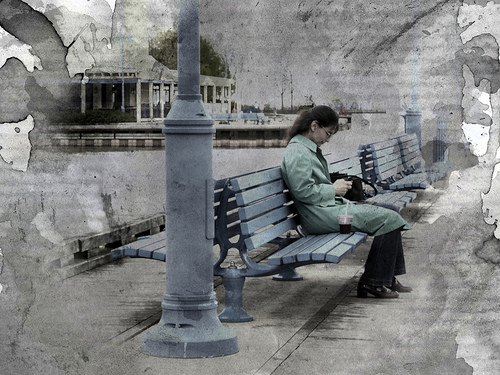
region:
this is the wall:
[271, 8, 387, 82]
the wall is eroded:
[257, 10, 493, 103]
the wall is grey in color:
[256, 19, 334, 66]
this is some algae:
[199, 43, 219, 73]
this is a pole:
[162, 5, 217, 330]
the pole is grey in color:
[171, 148, 199, 202]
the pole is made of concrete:
[176, 135, 204, 191]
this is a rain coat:
[301, 159, 313, 179]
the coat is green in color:
[293, 150, 306, 169]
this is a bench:
[243, 195, 294, 261]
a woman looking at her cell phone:
[280, 98, 400, 248]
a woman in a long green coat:
[278, 118, 405, 240]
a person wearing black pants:
[365, 233, 417, 277]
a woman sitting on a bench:
[222, 105, 395, 277]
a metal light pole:
[145, 20, 232, 331]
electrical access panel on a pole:
[197, 175, 219, 247]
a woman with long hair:
[280, 98, 347, 149]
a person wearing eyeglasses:
[320, 123, 336, 141]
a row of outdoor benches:
[176, 115, 435, 283]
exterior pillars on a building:
[83, 83, 170, 116]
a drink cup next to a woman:
[336, 198, 356, 234]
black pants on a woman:
[364, 224, 415, 285]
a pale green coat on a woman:
[280, 133, 406, 235]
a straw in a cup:
[342, 199, 351, 226]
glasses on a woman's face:
[319, 125, 336, 141]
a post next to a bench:
[138, 0, 241, 360]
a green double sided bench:
[112, 161, 408, 323]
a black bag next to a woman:
[324, 171, 380, 199]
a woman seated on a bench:
[280, 94, 413, 304]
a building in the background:
[48, 58, 252, 131]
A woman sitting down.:
[280, 102, 411, 299]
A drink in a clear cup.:
[339, 201, 353, 236]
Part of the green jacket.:
[293, 146, 312, 171]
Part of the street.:
[374, 335, 431, 368]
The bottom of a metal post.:
[141, 301, 238, 359]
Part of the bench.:
[256, 190, 281, 226]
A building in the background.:
[82, 48, 237, 129]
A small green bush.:
[51, 109, 136, 126]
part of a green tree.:
[157, 44, 174, 60]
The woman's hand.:
[332, 179, 351, 197]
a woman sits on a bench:
[220, 94, 418, 310]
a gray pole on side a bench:
[148, 3, 262, 362]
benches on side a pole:
[117, 107, 449, 364]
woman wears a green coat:
[273, 93, 418, 306]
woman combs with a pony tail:
[273, 95, 351, 182]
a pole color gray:
[147, 0, 249, 371]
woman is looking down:
[270, 100, 366, 201]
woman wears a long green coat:
[273, 92, 416, 303]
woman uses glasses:
[273, 90, 345, 176]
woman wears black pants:
[268, 90, 426, 314]